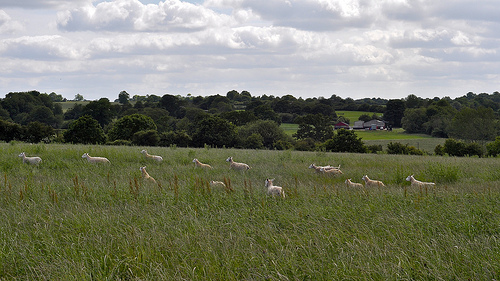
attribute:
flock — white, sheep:
[8, 138, 454, 228]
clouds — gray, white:
[67, 22, 274, 76]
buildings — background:
[326, 114, 389, 139]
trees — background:
[10, 104, 398, 165]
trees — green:
[135, 109, 228, 136]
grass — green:
[97, 202, 271, 272]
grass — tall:
[90, 202, 300, 278]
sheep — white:
[13, 149, 439, 196]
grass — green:
[205, 210, 311, 252]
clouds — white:
[59, 6, 221, 36]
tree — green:
[67, 99, 120, 144]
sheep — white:
[339, 174, 368, 194]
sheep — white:
[313, 156, 337, 175]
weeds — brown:
[119, 174, 146, 204]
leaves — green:
[442, 100, 477, 130]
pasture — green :
[3, 137, 496, 275]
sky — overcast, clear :
[0, 0, 498, 108]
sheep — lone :
[261, 175, 289, 204]